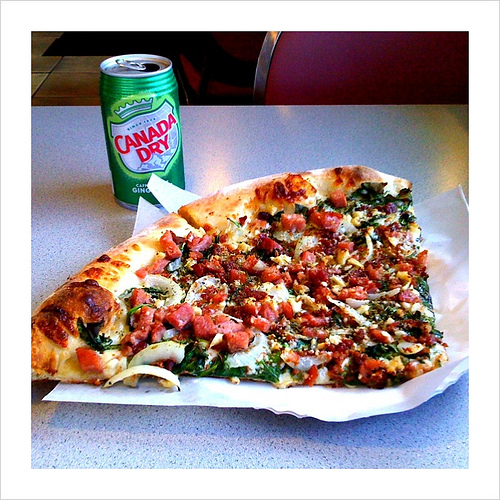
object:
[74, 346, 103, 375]
tomato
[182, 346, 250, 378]
oregano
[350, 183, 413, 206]
oregano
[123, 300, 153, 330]
spinach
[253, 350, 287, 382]
spinach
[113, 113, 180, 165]
canada dry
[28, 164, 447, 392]
slices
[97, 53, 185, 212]
can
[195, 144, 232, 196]
reflection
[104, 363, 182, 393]
onion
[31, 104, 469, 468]
table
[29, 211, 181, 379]
crust section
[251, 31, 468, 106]
chair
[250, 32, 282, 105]
frame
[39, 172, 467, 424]
plate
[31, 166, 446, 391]
food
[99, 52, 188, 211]
drink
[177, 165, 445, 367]
pizza slice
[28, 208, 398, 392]
pizza slice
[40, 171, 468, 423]
paper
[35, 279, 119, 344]
bubble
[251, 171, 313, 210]
bubble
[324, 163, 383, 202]
bubble